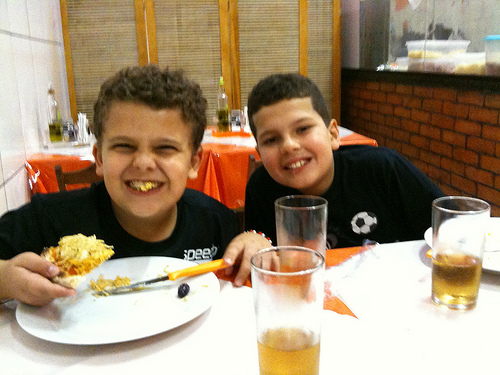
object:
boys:
[1, 64, 282, 306]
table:
[0, 237, 500, 375]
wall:
[343, 74, 500, 217]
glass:
[251, 246, 323, 374]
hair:
[93, 66, 208, 162]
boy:
[244, 73, 461, 250]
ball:
[351, 210, 379, 236]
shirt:
[243, 146, 459, 247]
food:
[41, 234, 116, 279]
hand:
[6, 251, 76, 309]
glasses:
[430, 196, 490, 313]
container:
[483, 33, 499, 77]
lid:
[485, 35, 498, 42]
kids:
[1, 66, 460, 307]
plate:
[14, 255, 221, 346]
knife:
[90, 259, 230, 296]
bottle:
[217, 76, 230, 132]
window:
[386, 0, 500, 61]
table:
[27, 122, 379, 163]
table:
[343, 62, 500, 91]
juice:
[256, 327, 322, 374]